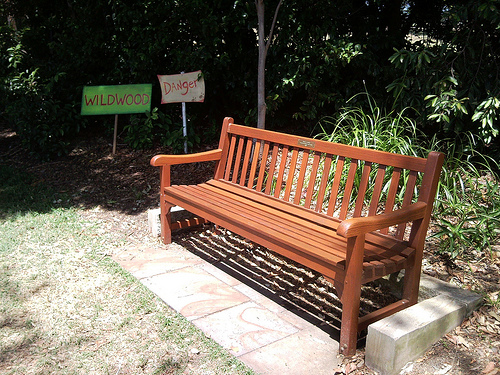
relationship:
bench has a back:
[149, 115, 443, 357] [217, 115, 442, 244]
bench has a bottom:
[149, 115, 443, 357] [165, 175, 420, 279]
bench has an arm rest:
[149, 115, 443, 357] [337, 200, 431, 238]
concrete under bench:
[111, 226, 433, 374] [149, 115, 443, 357]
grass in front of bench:
[0, 204, 252, 374] [149, 115, 443, 357]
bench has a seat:
[149, 115, 443, 357] [165, 175, 420, 279]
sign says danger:
[154, 69, 207, 103] [164, 80, 200, 96]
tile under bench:
[111, 226, 433, 374] [149, 115, 443, 357]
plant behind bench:
[310, 82, 491, 209] [149, 115, 443, 357]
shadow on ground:
[440, 337, 494, 375] [410, 236, 497, 375]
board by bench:
[78, 83, 153, 117] [149, 115, 443, 357]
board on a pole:
[78, 83, 153, 117] [110, 115, 119, 157]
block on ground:
[186, 297, 301, 361] [8, 211, 497, 374]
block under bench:
[186, 297, 301, 361] [149, 115, 443, 357]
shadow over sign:
[0, 115, 227, 223] [78, 83, 153, 117]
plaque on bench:
[295, 138, 318, 149] [149, 115, 443, 357]